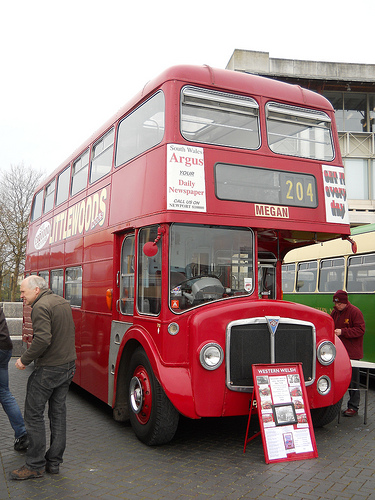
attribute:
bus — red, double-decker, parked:
[6, 51, 359, 450]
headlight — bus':
[178, 323, 360, 372]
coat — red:
[330, 305, 365, 357]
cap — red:
[333, 289, 346, 303]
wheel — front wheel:
[119, 349, 186, 437]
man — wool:
[16, 273, 85, 459]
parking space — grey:
[73, 425, 372, 495]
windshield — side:
[118, 226, 164, 316]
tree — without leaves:
[0, 160, 47, 299]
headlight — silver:
[197, 340, 224, 370]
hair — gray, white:
[17, 269, 52, 301]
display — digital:
[214, 158, 323, 211]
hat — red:
[330, 286, 349, 305]